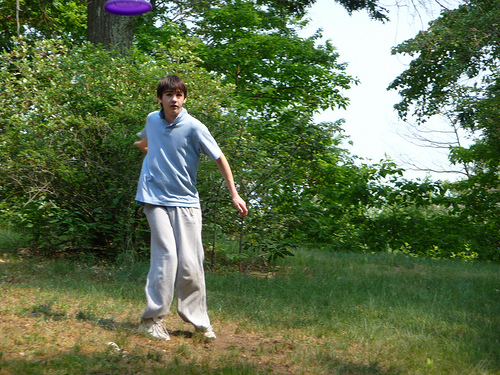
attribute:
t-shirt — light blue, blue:
[136, 107, 224, 210]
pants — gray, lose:
[141, 206, 212, 329]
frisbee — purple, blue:
[103, 0, 154, 15]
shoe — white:
[141, 319, 172, 340]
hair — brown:
[157, 78, 189, 100]